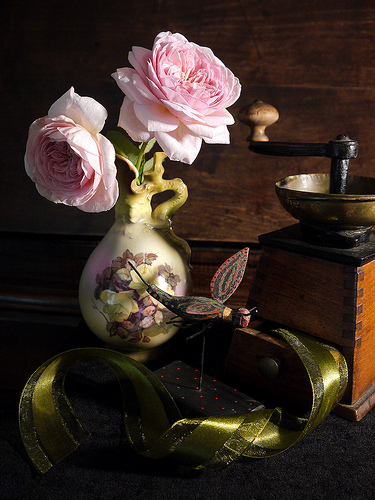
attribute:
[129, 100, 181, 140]
petal — is light, is pink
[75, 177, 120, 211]
flower petal — light pink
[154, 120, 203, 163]
flower petal — light pink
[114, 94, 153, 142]
flower petal — light pink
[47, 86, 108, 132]
flower petal — light pink, is pink, is light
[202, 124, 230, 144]
flower petal — light pink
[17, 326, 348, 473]
ribbon strip — gold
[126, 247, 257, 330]
bug — artwork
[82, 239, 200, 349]
decoration — golden, swirly, cloth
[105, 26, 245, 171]
flower — is light, is pink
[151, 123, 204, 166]
petal — is pink, is light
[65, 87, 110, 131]
petal — is pink, is light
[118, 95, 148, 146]
petal — is pink, is light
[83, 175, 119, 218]
petal — is pink, is light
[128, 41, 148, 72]
petal — is light, is pink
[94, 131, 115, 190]
petal — light pink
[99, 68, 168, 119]
petal — is pink, is light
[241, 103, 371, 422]
grinding mill — metal, wooden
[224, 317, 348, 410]
drawer — small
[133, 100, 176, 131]
flower petal — is pink, is light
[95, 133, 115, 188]
flower petal — is pink, is light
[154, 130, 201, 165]
flower petal — is pink, is light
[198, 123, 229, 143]
flower petal — is pink, is light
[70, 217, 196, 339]
vase — floral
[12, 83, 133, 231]
flower — is pink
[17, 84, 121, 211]
petal — is light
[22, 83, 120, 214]
flower — pink, light pink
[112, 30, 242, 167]
flower — pink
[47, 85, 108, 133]
petal — pink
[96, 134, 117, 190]
petal — pink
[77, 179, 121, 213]
petal — pink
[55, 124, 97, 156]
petal — pink